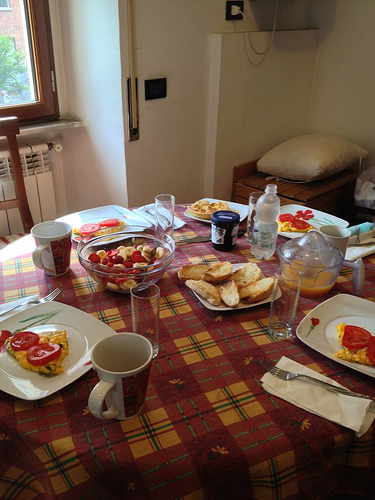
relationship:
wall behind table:
[172, 38, 215, 116] [2, 196, 363, 496]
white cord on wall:
[230, 3, 278, 56] [142, 2, 313, 172]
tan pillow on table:
[258, 133, 374, 178] [229, 162, 354, 215]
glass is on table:
[105, 274, 178, 331] [41, 242, 352, 434]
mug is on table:
[86, 321, 152, 422] [2, 196, 363, 496]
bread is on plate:
[220, 278, 241, 306] [180, 257, 278, 311]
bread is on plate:
[238, 274, 273, 302] [180, 257, 278, 311]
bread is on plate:
[226, 263, 260, 288] [180, 257, 278, 311]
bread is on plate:
[201, 259, 231, 282] [180, 257, 278, 311]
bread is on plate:
[183, 273, 221, 307] [180, 257, 278, 311]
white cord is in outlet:
[230, 3, 285, 55] [225, 2, 243, 21]